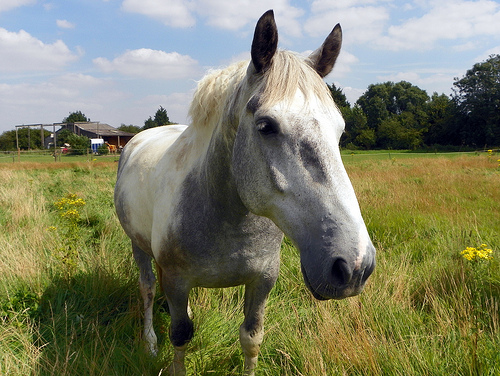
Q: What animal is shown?
A: A horse.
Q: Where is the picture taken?
A: A field.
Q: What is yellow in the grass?
A: Flowers.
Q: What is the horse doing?
A: Standing.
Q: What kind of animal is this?
A: Horse.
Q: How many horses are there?
A: 1.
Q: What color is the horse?
A: White.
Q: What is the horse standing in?
A: Grass.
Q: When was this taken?
A: Daytime.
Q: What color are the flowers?
A: Yellow.